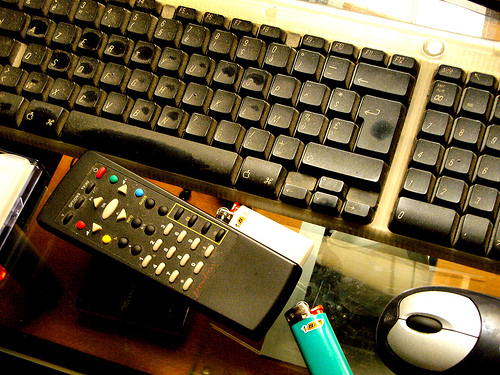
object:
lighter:
[281, 298, 358, 375]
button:
[310, 305, 324, 316]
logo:
[299, 316, 325, 333]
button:
[397, 290, 482, 340]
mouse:
[372, 278, 499, 375]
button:
[386, 317, 480, 373]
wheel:
[404, 314, 444, 334]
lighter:
[213, 199, 318, 268]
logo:
[233, 211, 249, 227]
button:
[229, 201, 241, 211]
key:
[354, 94, 407, 167]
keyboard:
[0, 0, 499, 278]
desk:
[1, 0, 500, 374]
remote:
[29, 150, 302, 342]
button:
[95, 166, 107, 181]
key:
[265, 102, 298, 136]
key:
[181, 51, 217, 87]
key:
[45, 77, 83, 112]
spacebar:
[58, 107, 246, 185]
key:
[267, 74, 302, 106]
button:
[134, 188, 144, 197]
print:
[190, 257, 220, 300]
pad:
[364, 62, 499, 271]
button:
[383, 195, 460, 247]